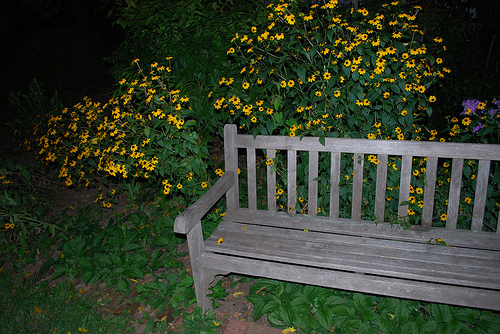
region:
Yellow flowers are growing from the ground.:
[43, 96, 185, 242]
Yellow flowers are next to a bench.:
[58, 78, 451, 268]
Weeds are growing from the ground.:
[97, 240, 182, 327]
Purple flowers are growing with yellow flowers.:
[443, 86, 498, 133]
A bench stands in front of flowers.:
[213, 106, 497, 331]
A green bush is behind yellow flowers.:
[113, 8, 235, 90]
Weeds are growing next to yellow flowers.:
[63, 213, 160, 308]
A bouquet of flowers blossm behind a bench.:
[36, 0, 495, 168]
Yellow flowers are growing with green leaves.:
[44, 71, 210, 196]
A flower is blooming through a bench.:
[393, 196, 463, 266]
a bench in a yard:
[152, 63, 483, 308]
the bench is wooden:
[159, 129, 485, 319]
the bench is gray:
[144, 135, 473, 307]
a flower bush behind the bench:
[176, 19, 436, 108]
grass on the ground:
[17, 192, 187, 327]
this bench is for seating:
[177, 119, 470, 311]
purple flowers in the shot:
[436, 82, 492, 137]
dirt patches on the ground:
[20, 182, 170, 314]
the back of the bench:
[219, 137, 485, 232]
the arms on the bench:
[164, 167, 251, 261]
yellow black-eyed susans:
[334, 36, 362, 68]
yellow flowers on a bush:
[310, 78, 327, 107]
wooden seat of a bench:
[251, 210, 364, 292]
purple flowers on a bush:
[456, 90, 487, 134]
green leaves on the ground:
[74, 222, 140, 275]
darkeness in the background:
[44, 26, 78, 73]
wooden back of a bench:
[231, 142, 486, 239]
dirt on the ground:
[231, 297, 247, 321]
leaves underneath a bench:
[231, 280, 321, 332]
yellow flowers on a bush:
[116, 83, 136, 110]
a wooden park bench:
[168, 127, 498, 322]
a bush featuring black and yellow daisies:
[6, 67, 213, 217]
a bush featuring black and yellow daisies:
[208, 10, 497, 155]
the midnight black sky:
[10, 8, 111, 80]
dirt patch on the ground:
[222, 281, 280, 332]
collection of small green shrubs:
[58, 220, 184, 301]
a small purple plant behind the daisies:
[456, 91, 499, 146]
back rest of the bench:
[226, 129, 499, 222]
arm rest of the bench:
[166, 185, 250, 310]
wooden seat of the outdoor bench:
[231, 208, 497, 308]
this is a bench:
[178, 120, 496, 331]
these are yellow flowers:
[95, 105, 141, 152]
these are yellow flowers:
[88, 130, 140, 164]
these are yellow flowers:
[159, 118, 222, 194]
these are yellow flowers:
[255, 37, 312, 119]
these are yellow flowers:
[370, 38, 420, 113]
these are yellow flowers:
[198, 60, 263, 128]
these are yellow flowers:
[107, 152, 143, 209]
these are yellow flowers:
[147, 71, 219, 173]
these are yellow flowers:
[64, 105, 186, 197]